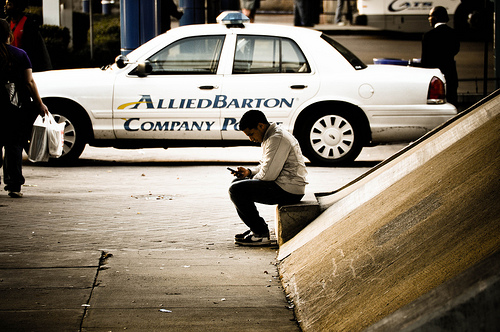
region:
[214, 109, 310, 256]
man sitting on the sidewalk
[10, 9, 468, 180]
white car on the road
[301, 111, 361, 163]
silver rims on the tire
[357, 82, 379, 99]
small circle where you insert gas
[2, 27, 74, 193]
person carrying two bags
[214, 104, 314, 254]
man looking at his phone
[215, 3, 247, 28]
blue lights on top of the vehicle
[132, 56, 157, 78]
mirror on the side of the car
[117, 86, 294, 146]
logo painted on the doors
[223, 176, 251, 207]
knees are bent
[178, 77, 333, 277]
the man is texting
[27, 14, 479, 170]
the car is white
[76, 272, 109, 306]
par tof a line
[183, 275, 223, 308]
par tof a path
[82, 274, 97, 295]
par tof a line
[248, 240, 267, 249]
part of a sole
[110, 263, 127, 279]
part of a floor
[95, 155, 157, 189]
this is the ground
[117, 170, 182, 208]
the ground is clean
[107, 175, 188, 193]
the ground is white in color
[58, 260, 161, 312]
the ground is made of stone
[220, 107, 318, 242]
this is a man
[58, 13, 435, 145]
this is a car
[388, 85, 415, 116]
the car is white in color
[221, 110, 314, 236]
the man is seated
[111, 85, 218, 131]
these are some writings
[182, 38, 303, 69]
these are two doors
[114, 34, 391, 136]
this is a car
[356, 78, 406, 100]
the car is white in color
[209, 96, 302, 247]
this is a man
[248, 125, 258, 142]
the man is light skinned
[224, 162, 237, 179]
this is a phone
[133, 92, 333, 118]
this is a writing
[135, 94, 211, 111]
the writing is in blue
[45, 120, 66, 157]
this is a paper bag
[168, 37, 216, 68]
this is a window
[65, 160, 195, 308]
this is the ground